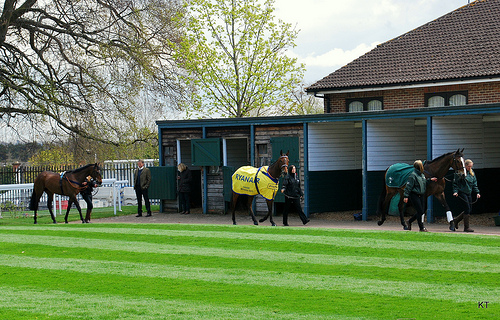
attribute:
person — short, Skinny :
[278, 162, 315, 227]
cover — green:
[385, 157, 418, 189]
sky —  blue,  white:
[0, 0, 468, 143]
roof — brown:
[346, 6, 497, 78]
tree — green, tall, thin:
[147, 7, 299, 109]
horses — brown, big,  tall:
[29, 157, 468, 229]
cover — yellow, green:
[231, 164, 281, 201]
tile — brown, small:
[457, 52, 469, 55]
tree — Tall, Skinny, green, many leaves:
[25, 23, 260, 117]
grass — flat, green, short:
[211, 230, 299, 302]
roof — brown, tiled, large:
[304, 26, 498, 84]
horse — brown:
[15, 149, 125, 231]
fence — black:
[1, 160, 161, 213]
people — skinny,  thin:
[399, 159, 481, 232]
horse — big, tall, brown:
[20, 148, 126, 216]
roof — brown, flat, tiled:
[437, 20, 496, 64]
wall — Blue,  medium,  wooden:
[324, 100, 325, 165]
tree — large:
[1, 3, 310, 109]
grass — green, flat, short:
[69, 225, 352, 307]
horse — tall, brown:
[27, 160, 102, 222]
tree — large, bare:
[0, 0, 171, 147]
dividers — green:
[420, 125, 494, 215]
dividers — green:
[359, 126, 426, 213]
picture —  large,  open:
[2, 3, 492, 318]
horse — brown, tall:
[23, 151, 132, 228]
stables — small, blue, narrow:
[274, 112, 425, 199]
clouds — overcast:
[299, 2, 356, 68]